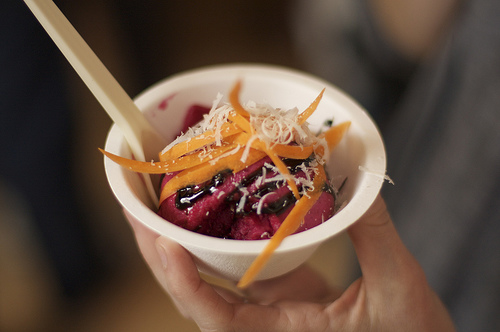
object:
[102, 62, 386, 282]
bowl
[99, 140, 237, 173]
carrots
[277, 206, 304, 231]
meat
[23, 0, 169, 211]
utensil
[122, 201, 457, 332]
hand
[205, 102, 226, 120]
cheese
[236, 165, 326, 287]
carrot piece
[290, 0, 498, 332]
person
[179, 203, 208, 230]
strawberries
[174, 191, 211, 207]
jam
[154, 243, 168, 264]
nail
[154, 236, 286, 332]
finger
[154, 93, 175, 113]
stain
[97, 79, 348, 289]
fruit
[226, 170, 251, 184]
coconut